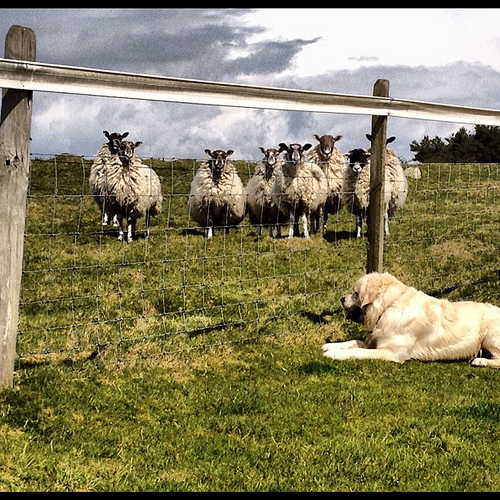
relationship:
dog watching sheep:
[323, 271, 499, 368] [103, 140, 161, 240]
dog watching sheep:
[323, 271, 499, 368] [187, 148, 246, 235]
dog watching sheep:
[323, 271, 499, 368] [273, 143, 328, 237]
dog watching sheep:
[323, 271, 499, 368] [344, 148, 409, 240]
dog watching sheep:
[323, 271, 499, 368] [308, 132, 347, 217]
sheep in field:
[343, 149, 405, 235] [0, 148, 497, 497]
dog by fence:
[321, 271, 500, 370] [5, 20, 498, 385]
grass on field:
[0, 154, 497, 497] [0, 148, 497, 497]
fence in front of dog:
[5, 20, 498, 385] [318, 268, 498, 362]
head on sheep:
[95, 134, 133, 151] [76, 139, 138, 210]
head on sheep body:
[312, 132, 343, 160] [306, 145, 346, 214]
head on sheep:
[339, 128, 394, 203] [314, 114, 449, 246]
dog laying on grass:
[321, 271, 500, 370] [244, 421, 313, 478]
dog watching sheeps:
[321, 271, 500, 370] [85, 120, 413, 245]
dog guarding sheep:
[321, 271, 500, 370] [279, 143, 326, 240]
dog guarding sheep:
[321, 271, 500, 370] [306, 118, 345, 225]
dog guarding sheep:
[321, 271, 500, 370] [335, 143, 392, 240]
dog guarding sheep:
[321, 271, 500, 370] [102, 139, 151, 248]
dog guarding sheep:
[321, 271, 500, 370] [91, 126, 140, 233]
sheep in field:
[87, 128, 407, 241] [0, 148, 497, 497]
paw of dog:
[322, 349, 349, 361] [318, 268, 498, 362]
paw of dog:
[320, 342, 340, 351] [318, 268, 498, 362]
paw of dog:
[471, 355, 488, 367] [318, 268, 498, 362]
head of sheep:
[313, 134, 343, 160] [305, 134, 349, 231]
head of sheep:
[343, 148, 371, 172] [344, 147, 392, 230]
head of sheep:
[279, 140, 307, 167] [250, 141, 292, 237]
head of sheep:
[204, 147, 240, 174] [187, 141, 244, 231]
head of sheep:
[114, 139, 140, 168] [98, 143, 163, 229]